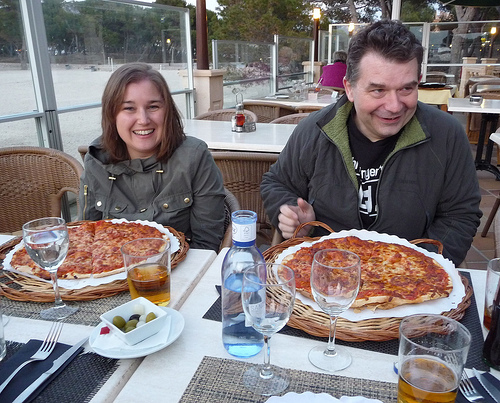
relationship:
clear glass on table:
[240, 264, 293, 393] [5, 300, 490, 401]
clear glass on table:
[311, 248, 358, 369] [5, 300, 490, 401]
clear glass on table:
[240, 264, 295, 394] [0, 239, 498, 401]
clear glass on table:
[308, 248, 361, 372] [0, 239, 498, 401]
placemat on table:
[173, 349, 440, 402] [141, 294, 382, 402]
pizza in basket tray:
[5, 219, 170, 277] [0, 252, 185, 299]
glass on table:
[244, 271, 285, 391] [178, 306, 223, 396]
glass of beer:
[395, 313, 473, 403] [122, 268, 181, 305]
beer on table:
[122, 268, 181, 305] [0, 239, 498, 401]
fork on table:
[293, 182, 358, 244] [26, 171, 468, 397]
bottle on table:
[220, 209, 267, 355] [0, 239, 498, 401]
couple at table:
[79, 32, 481, 325] [22, 137, 479, 399]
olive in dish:
[110, 314, 129, 331] [96, 293, 168, 347]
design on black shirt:
[350, 152, 382, 218] [337, 107, 412, 229]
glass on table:
[395, 313, 475, 401] [0, 239, 498, 401]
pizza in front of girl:
[9, 220, 169, 280] [75, 62, 225, 253]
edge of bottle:
[252, 277, 272, 305] [220, 209, 266, 356]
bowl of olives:
[84, 289, 170, 349] [111, 298, 156, 329]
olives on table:
[111, 298, 156, 329] [0, 202, 497, 401]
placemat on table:
[173, 354, 401, 403] [0, 239, 498, 401]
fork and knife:
[0, 321, 62, 394] [31, 331, 122, 391]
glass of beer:
[395, 313, 475, 401] [395, 358, 461, 401]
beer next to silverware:
[395, 358, 461, 401] [443, 349, 498, 401]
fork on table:
[0, 322, 72, 394] [65, 103, 478, 390]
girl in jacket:
[75, 60, 228, 253] [97, 134, 220, 230]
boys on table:
[22, 216, 80, 321] [14, 277, 257, 386]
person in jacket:
[312, 49, 359, 100] [312, 61, 339, 104]